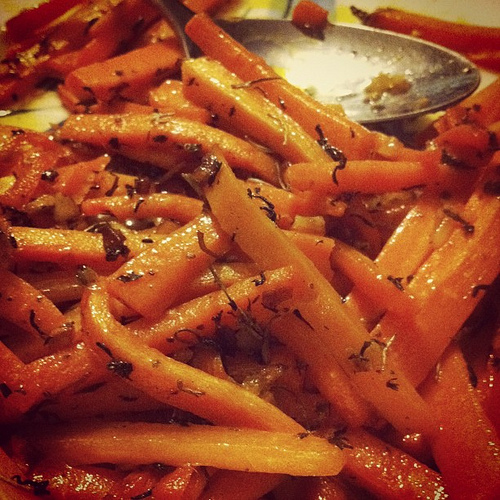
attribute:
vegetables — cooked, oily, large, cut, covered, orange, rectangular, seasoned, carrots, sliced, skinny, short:
[77, 133, 330, 294]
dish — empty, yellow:
[23, 97, 60, 130]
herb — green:
[178, 136, 227, 188]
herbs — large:
[162, 143, 233, 191]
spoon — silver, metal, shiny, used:
[234, 18, 489, 124]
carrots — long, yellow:
[42, 160, 288, 355]